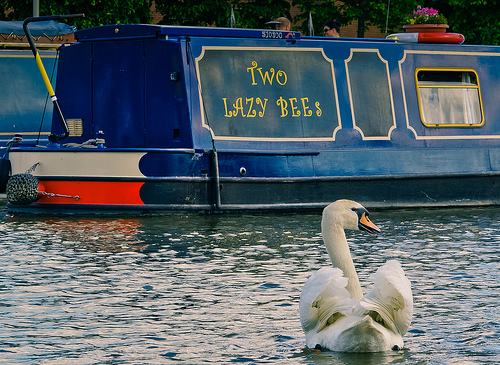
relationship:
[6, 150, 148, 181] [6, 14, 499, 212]
stripe on boat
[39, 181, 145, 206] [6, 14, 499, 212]
stripe on boat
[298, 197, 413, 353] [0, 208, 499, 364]
swan on water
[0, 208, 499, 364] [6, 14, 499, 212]
water around a boat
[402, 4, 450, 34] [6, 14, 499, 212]
plant on a boat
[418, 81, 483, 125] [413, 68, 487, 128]
curtain in a window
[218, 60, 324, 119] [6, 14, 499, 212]
name written on a boat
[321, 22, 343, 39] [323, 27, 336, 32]
man wearing sunglasses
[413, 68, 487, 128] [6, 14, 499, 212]
window on a boat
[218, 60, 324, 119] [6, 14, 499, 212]
name on boat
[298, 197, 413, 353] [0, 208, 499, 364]
swan in water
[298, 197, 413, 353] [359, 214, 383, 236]
swan has a beak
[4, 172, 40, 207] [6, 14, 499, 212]
rope at end of boat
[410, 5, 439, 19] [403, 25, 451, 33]
flowers are in a pot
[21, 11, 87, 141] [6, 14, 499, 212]
pole sticking out of boat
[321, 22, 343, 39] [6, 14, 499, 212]
man over boat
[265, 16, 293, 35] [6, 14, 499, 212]
man over boat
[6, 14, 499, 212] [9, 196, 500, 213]
boat has a bottom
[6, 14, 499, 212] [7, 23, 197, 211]
boat has a back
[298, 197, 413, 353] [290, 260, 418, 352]
swan has feathers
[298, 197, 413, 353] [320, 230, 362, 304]
swan has a neck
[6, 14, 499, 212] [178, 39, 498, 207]
boat has a side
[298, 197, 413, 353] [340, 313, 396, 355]
swan has a back